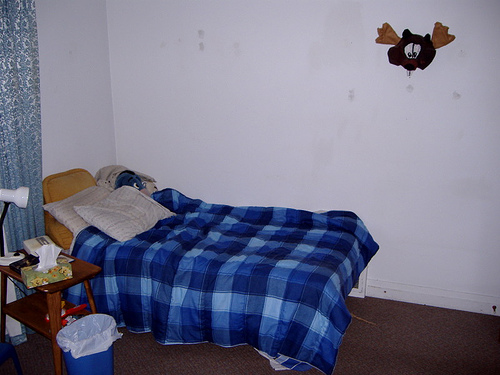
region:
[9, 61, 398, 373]
picture of a bedroom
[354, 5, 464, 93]
some kind of character on the wall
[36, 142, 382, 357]
the bed has a blue checkered spread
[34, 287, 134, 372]
this is a blue garbage can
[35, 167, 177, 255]
these pillows do not have a cover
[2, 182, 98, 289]
a light on the night stand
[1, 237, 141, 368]
a nightstand beside the bed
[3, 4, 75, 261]
blue curtains in the background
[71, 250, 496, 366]
a brown carpet on the floor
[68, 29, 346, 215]
white walls above the bed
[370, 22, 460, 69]
a cartoon character with ears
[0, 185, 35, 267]
a white table lamp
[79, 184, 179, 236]
a white pillow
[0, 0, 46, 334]
a long blue and white curtain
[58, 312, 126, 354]
a white trash bag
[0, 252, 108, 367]
a brown table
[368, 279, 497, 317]
a piece of white wall trim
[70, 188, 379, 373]
a checkered blue comforter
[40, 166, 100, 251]
part of a yellow pillow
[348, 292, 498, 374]
red carpet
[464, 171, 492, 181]
part of a wall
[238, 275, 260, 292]
edge of a bed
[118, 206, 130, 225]
part of a pillow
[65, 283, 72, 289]
part of a table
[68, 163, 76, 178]
edge of a bed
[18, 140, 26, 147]
part of a curtain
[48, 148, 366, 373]
A twin bed in the corner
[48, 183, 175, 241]
Two pillows on a bed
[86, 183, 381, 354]
A blue comforter on a bed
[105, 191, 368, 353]
A blue plaid comforter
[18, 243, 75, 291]
A box of tissues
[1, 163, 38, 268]
A white lamp on a stand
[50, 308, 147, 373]
A blue garbage can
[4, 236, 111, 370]
A small wooden table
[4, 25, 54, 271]
A curtain hanging at a window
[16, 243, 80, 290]
A flowered box of tissue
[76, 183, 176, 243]
a white bed pillow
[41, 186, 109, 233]
a white bed pillow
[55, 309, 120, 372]
a blue lined trash can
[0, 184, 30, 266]
a white desk lamp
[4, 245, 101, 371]
a small wooden table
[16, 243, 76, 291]
a box of facial tissue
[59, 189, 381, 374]
a striped blue comforter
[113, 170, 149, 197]
a plush Eeyore doll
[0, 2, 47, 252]
a light blue curtain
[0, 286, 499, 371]
a dark brown carpet